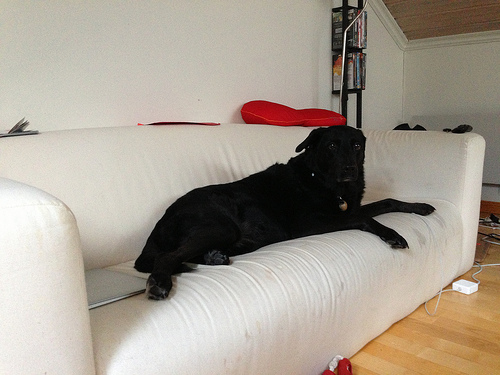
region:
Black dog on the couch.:
[112, 107, 443, 334]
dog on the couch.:
[91, 53, 418, 305]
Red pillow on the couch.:
[201, 69, 444, 215]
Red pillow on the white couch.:
[193, 64, 412, 178]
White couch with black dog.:
[149, 84, 441, 364]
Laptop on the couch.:
[47, 232, 189, 344]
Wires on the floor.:
[415, 224, 499, 329]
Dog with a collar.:
[288, 116, 378, 239]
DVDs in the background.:
[318, 1, 406, 127]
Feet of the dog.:
[101, 213, 289, 343]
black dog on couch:
[126, 117, 441, 306]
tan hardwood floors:
[325, 223, 494, 373]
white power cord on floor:
[420, 234, 495, 319]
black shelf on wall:
[325, 0, 375, 132]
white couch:
[0, 97, 492, 374]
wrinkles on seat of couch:
[208, 266, 330, 324]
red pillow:
[234, 94, 355, 136]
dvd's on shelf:
[330, 6, 372, 50]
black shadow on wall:
[405, 99, 494, 199]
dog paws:
[377, 188, 446, 259]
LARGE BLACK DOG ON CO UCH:
[136, 119, 441, 301]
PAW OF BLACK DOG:
[381, 230, 407, 250]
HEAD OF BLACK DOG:
[296, 123, 376, 188]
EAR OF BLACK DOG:
[296, 131, 312, 160]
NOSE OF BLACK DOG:
[342, 173, 357, 183]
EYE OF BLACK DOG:
[325, 135, 345, 154]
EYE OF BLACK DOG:
[348, 139, 364, 151]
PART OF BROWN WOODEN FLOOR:
[421, 328, 482, 368]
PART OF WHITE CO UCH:
[184, 308, 301, 344]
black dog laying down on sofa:
[122, 118, 439, 306]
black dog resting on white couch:
[133, 119, 438, 303]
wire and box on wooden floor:
[416, 253, 499, 328]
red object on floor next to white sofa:
[318, 351, 362, 371]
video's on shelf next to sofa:
[326, 3, 378, 98]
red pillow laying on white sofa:
[236, 88, 364, 131]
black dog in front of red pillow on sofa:
[138, 122, 440, 305]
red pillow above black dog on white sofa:
[233, 97, 355, 134]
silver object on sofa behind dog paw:
[71, 263, 159, 319]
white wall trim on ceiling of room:
[353, 0, 497, 57]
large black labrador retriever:
[136, 124, 437, 299]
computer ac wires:
[428, 261, 498, 310]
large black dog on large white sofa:
[0, 121, 485, 373]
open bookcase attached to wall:
[329, 31, 368, 130]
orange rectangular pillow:
[240, 99, 344, 126]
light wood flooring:
[347, 227, 497, 372]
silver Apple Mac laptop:
[86, 265, 144, 308]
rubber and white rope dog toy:
[320, 354, 352, 374]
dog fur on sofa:
[241, 327, 253, 337]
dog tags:
[338, 197, 347, 210]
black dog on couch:
[117, 93, 458, 308]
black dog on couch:
[123, 96, 443, 308]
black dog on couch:
[126, 102, 442, 322]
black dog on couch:
[126, 85, 457, 317]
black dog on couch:
[130, 92, 458, 316]